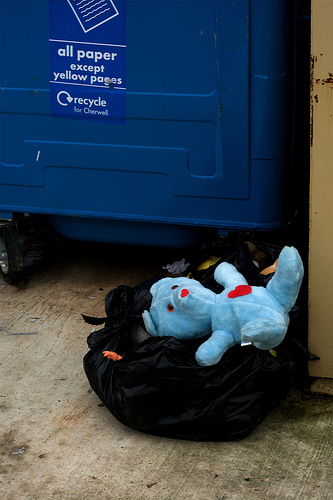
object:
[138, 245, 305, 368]
teddy bear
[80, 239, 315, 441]
bag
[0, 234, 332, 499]
ground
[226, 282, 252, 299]
heart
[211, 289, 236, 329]
chest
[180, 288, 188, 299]
heart nose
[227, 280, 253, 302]
red heart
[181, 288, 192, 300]
red heart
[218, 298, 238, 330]
plushie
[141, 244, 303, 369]
bear